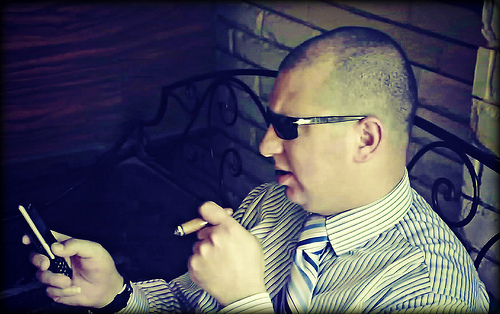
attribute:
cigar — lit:
[174, 205, 239, 235]